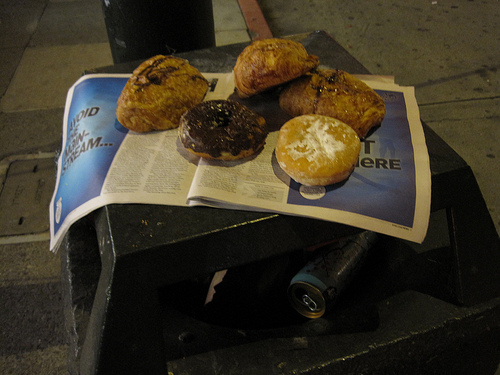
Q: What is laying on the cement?
A: Can.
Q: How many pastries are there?
A: 5.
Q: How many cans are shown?
A: 1.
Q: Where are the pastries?
A: On magazine.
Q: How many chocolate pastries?
A: 1.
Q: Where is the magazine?
A: On black box.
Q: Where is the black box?
A: On sidewalk.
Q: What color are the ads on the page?
A: Blue.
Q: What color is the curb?
A: Red.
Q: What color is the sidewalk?
A: Grey.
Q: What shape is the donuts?
A: Round.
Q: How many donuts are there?
A: Two.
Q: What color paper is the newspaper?
A: Blue and white.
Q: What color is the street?
A: Gray.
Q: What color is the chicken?
A: Brown.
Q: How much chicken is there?
A: Three.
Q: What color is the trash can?
A: Black.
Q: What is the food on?
A: A newspaper.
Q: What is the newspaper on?
A: A trash can.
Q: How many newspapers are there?
A: One.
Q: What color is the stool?
A: Black.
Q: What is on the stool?
A: Newspaper and donuts.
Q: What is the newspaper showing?
A: Article.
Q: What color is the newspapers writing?
A: Black.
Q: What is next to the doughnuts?
A: Pastry.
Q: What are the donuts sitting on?
A: Magazine.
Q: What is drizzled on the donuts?
A: Chocolate.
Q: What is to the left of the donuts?
A: Sidewalk.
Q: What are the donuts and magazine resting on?
A: Black stool.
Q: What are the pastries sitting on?
A: A newspaper.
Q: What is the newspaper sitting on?
A: A garbage can.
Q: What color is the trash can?
A: Black.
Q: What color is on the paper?
A: Black, white, blue.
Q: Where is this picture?
A: On a street.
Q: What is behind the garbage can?
A: A pole.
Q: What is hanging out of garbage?
A: A can.